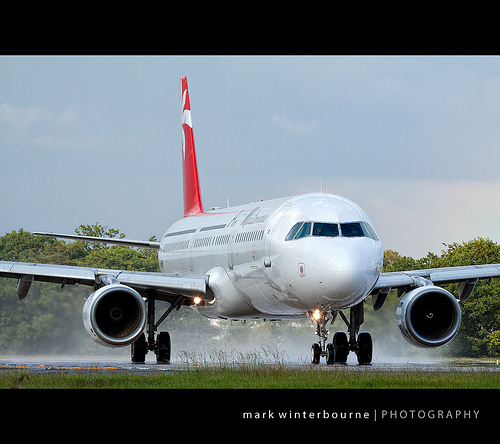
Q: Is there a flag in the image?
A: No, there are no flags.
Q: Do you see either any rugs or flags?
A: No, there are no flags or rugs.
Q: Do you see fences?
A: No, there are no fences.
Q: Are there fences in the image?
A: No, there are no fences.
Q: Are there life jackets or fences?
A: No, there are no fences or life jackets.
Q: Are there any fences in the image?
A: No, there are no fences.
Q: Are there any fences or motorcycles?
A: No, there are no fences or motorcycles.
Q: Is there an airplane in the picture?
A: Yes, there is an airplane.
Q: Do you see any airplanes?
A: Yes, there is an airplane.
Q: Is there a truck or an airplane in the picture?
A: Yes, there is an airplane.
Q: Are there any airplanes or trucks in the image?
A: Yes, there is an airplane.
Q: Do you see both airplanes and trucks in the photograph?
A: No, there is an airplane but no trucks.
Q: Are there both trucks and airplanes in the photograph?
A: No, there is an airplane but no trucks.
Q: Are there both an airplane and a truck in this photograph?
A: No, there is an airplane but no trucks.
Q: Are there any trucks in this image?
A: No, there are no trucks.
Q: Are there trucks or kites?
A: No, there are no trucks or kites.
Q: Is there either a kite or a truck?
A: No, there are no trucks or kites.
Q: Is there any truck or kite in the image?
A: No, there are no trucks or kites.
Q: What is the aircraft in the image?
A: The aircraft is an airplane.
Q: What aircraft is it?
A: The aircraft is an airplane.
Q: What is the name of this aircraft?
A: This is an airplane.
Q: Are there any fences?
A: No, there are no fences.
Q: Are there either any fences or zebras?
A: No, there are no fences or zebras.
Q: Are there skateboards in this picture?
A: No, there are no skateboards.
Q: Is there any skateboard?
A: No, there are no skateboards.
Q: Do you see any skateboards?
A: No, there are no skateboards.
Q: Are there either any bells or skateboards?
A: No, there are no skateboards or bells.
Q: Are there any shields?
A: No, there are no shields.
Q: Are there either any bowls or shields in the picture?
A: No, there are no shields or bowls.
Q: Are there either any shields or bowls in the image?
A: No, there are no shields or bowls.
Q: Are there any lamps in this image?
A: No, there are no lamps.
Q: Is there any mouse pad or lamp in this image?
A: No, there are no lamps or mouse pads.